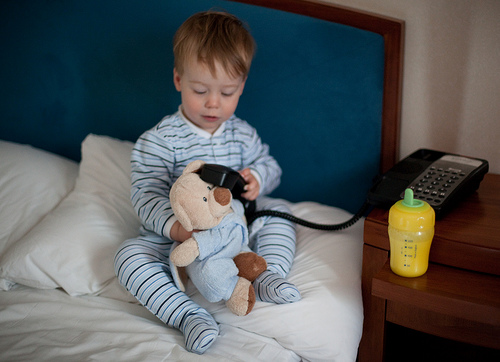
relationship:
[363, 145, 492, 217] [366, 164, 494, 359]
phone on top of table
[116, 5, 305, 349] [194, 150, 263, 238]
boy with phone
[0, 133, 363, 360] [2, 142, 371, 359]
pillow on bed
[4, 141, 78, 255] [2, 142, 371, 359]
pillow on bed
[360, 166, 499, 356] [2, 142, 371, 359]
nightstand beside bed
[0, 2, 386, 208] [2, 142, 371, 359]
headrest on bed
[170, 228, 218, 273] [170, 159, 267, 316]
arm on animal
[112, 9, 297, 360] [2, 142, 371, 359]
kid sitting on bed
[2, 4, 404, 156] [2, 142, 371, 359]
headboard on bed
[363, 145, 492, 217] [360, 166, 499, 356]
phone on nightstand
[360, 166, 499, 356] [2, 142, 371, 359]
nightstand next to bed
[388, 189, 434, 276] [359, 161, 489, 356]
cup on nighttable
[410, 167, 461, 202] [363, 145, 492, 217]
buttons on phone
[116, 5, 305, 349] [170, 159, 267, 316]
boy holding animal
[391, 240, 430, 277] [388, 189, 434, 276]
milk in cup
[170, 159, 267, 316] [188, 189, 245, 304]
animal wearing outfit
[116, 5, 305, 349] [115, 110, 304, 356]
boy wearing pajamas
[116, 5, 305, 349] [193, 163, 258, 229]
boy putting phone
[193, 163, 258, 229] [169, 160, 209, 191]
phone on bear's ear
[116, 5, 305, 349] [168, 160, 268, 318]
boy playing with teddy bear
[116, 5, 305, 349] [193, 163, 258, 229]
boy holding phone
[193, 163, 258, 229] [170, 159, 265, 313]
phone to animal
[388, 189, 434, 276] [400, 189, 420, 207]
cup has top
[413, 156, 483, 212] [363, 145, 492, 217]
keyboard of phone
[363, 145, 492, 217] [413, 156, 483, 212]
phone has keyboard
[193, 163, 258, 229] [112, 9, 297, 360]
phone held by kid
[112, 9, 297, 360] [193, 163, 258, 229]
kid holding phone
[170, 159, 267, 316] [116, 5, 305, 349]
animal held by boy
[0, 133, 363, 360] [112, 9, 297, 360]
pillow sat on by kid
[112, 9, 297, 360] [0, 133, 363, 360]
kid sitting on pillow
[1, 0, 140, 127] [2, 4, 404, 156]
background on headboard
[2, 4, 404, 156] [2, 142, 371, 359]
headboard of bed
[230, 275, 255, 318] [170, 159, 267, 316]
foot of animal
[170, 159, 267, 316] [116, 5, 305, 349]
animal being held by boy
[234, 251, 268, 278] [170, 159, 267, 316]
foot of animal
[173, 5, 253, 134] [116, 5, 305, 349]
head of boy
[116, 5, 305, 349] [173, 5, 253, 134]
boy has head